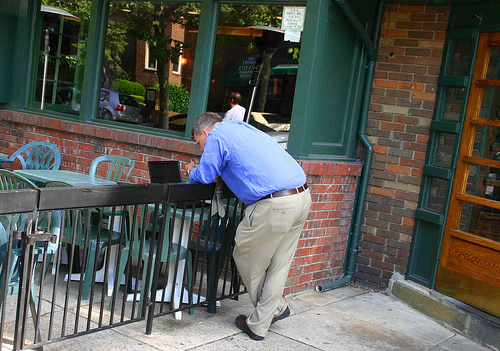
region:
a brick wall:
[315, 178, 352, 250]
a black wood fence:
[0, 168, 210, 348]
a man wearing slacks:
[210, 162, 322, 349]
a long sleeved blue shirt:
[177, 107, 316, 219]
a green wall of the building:
[288, 1, 376, 179]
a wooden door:
[418, 0, 498, 318]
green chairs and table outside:
[0, 125, 141, 192]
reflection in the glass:
[96, 0, 182, 140]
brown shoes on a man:
[206, 286, 301, 347]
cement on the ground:
[320, 307, 385, 340]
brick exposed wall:
[401, 37, 417, 197]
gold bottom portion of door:
[415, 250, 482, 305]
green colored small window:
[413, 32, 445, 287]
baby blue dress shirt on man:
[196, 117, 316, 202]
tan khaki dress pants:
[249, 196, 304, 321]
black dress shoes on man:
[240, 301, 301, 348]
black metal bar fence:
[29, 162, 217, 317]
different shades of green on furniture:
[11, 134, 101, 195]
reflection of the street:
[74, 9, 220, 124]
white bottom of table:
[147, 196, 220, 319]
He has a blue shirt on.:
[183, 106, 321, 233]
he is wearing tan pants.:
[210, 187, 342, 340]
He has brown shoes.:
[229, 280, 300, 340]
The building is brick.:
[316, 209, 386, 282]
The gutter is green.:
[336, 124, 366, 311]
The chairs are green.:
[20, 127, 120, 220]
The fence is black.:
[7, 163, 349, 335]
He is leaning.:
[184, 107, 332, 347]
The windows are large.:
[20, 27, 307, 172]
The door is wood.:
[436, 188, 496, 290]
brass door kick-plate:
[422, 258, 497, 324]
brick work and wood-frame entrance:
[400, 56, 495, 321]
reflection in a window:
[101, 0, 188, 120]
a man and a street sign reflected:
[221, 41, 271, 116]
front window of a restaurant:
[0, 0, 455, 111]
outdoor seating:
[1, 106, 157, 341]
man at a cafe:
[145, 90, 325, 350]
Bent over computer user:
[140, 95, 316, 215]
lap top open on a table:
[137, 145, 197, 215]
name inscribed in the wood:
[425, 145, 496, 332]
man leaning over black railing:
[141, 91, 327, 331]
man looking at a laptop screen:
[144, 83, 319, 340]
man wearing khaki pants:
[193, 101, 319, 344]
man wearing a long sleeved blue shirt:
[177, 94, 319, 331]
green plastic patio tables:
[12, 126, 150, 290]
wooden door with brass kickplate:
[426, 17, 496, 312]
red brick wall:
[310, 158, 360, 276]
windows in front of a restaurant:
[37, 8, 294, 128]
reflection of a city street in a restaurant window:
[47, 4, 280, 132]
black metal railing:
[11, 186, 226, 323]